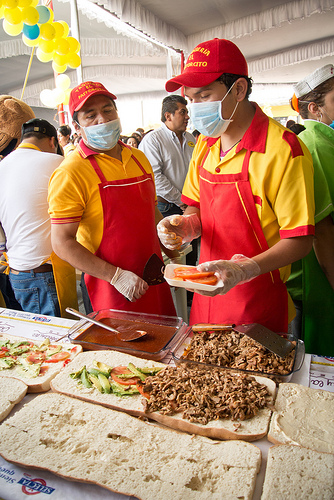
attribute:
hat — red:
[161, 34, 260, 86]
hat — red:
[69, 77, 119, 115]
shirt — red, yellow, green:
[169, 117, 320, 320]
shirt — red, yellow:
[53, 146, 159, 272]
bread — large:
[1, 336, 334, 500]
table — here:
[3, 307, 334, 499]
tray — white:
[159, 260, 227, 296]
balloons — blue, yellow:
[3, 0, 85, 79]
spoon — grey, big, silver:
[64, 307, 148, 343]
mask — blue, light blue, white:
[187, 86, 249, 146]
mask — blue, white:
[78, 117, 129, 151]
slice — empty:
[6, 395, 246, 500]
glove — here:
[106, 263, 148, 303]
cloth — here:
[5, 306, 334, 499]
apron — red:
[196, 135, 294, 324]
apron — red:
[80, 145, 174, 316]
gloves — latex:
[161, 212, 249, 301]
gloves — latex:
[108, 267, 150, 300]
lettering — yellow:
[180, 49, 216, 72]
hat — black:
[19, 120, 64, 153]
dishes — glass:
[69, 303, 304, 372]